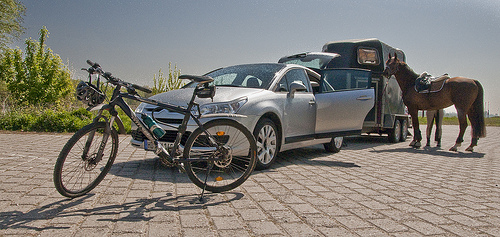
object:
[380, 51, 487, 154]
horse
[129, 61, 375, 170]
car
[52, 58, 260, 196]
bicycle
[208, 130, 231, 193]
lights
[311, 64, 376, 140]
door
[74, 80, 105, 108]
helmet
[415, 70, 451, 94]
saddle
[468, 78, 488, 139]
tail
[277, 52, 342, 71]
trunk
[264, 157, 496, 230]
pavement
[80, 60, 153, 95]
handlebars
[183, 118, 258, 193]
wheel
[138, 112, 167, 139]
bottle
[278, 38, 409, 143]
trailer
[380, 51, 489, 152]
right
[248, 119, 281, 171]
wheel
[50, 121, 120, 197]
tire